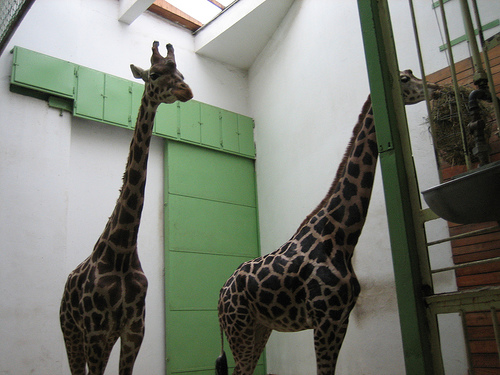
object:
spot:
[308, 238, 335, 264]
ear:
[129, 63, 151, 81]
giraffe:
[58, 41, 192, 375]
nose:
[168, 80, 194, 96]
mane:
[289, 87, 374, 245]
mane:
[92, 80, 149, 253]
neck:
[283, 103, 379, 249]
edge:
[260, 326, 316, 334]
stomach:
[242, 278, 312, 332]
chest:
[324, 250, 362, 327]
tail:
[213, 322, 227, 375]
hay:
[426, 100, 487, 167]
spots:
[258, 272, 281, 291]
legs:
[313, 315, 348, 375]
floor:
[276, 89, 333, 128]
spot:
[340, 177, 358, 199]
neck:
[96, 104, 161, 254]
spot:
[305, 231, 335, 263]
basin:
[421, 160, 499, 225]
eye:
[147, 72, 161, 80]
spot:
[132, 144, 146, 162]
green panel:
[163, 190, 261, 257]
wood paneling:
[460, 308, 496, 373]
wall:
[446, 219, 500, 375]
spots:
[303, 278, 324, 300]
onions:
[157, 81, 177, 92]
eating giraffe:
[215, 69, 441, 374]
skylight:
[145, 0, 240, 32]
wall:
[254, 67, 353, 115]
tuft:
[213, 354, 227, 374]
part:
[326, 249, 363, 302]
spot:
[294, 229, 319, 255]